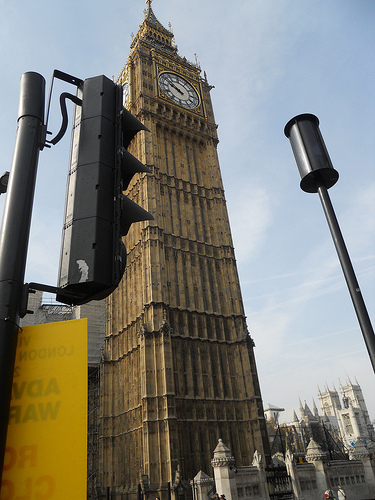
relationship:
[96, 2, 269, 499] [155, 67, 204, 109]
tower has clock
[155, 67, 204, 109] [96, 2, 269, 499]
clock on tower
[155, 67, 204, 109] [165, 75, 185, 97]
clock has hands